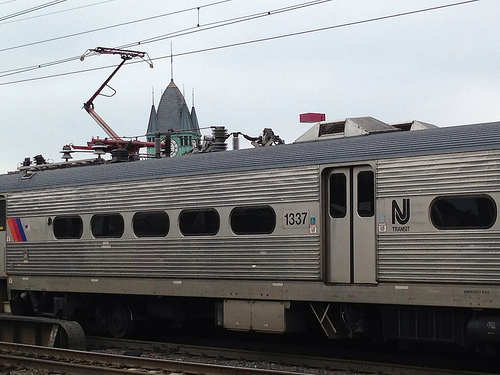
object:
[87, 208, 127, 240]
window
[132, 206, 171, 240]
window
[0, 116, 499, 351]
train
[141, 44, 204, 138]
church roof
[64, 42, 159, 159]
equipment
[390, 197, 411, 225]
logo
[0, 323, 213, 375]
track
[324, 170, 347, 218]
window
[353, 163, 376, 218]
window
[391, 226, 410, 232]
letter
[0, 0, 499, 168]
sky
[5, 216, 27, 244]
color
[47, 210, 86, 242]
window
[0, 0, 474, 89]
cables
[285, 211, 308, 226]
number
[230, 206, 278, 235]
window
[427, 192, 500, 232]
window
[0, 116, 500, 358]
car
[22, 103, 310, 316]
car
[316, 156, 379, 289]
door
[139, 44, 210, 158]
tower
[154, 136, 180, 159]
clock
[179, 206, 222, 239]
window